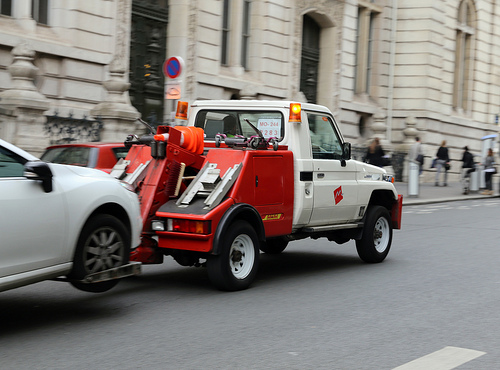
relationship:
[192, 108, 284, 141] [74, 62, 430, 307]
window of truck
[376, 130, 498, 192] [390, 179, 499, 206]
people walking pavement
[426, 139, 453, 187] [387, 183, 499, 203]
people on pavement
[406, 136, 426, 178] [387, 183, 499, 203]
people on pavement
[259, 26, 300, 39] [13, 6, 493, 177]
stone on building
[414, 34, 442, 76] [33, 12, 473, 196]
stone on building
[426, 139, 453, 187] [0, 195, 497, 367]
people walking on street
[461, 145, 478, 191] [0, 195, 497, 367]
people walking on street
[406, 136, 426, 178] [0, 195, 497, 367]
people walking on street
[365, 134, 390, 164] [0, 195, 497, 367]
people walking on street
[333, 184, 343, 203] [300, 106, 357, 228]
logo on side of door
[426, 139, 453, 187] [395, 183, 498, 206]
people walking on pavement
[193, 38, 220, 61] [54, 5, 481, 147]
stone on building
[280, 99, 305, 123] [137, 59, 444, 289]
light on side of car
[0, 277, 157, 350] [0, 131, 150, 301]
shadow underneath car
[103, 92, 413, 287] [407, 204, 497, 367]
tow truck driving on street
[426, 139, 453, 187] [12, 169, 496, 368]
people walking on pavement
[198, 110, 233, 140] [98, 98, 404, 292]
window on car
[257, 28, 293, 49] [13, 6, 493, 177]
stone on building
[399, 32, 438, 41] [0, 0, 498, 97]
stone on building